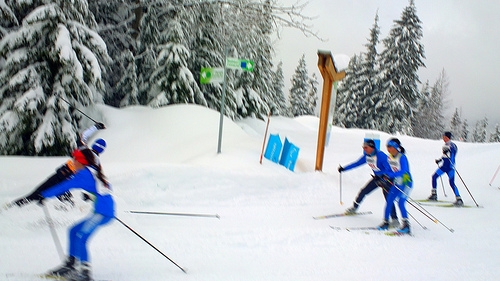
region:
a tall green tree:
[362, 1, 432, 134]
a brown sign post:
[298, 40, 360, 190]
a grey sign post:
[202, 48, 247, 160]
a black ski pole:
[74, 181, 208, 278]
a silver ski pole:
[376, 166, 459, 248]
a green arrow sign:
[191, 58, 228, 88]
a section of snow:
[188, 170, 264, 242]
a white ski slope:
[21, 84, 489, 278]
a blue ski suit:
[371, 141, 426, 238]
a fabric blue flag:
[249, 111, 344, 186]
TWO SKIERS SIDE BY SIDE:
[307, 126, 457, 250]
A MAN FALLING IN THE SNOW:
[1, 85, 121, 212]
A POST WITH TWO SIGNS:
[192, 35, 260, 162]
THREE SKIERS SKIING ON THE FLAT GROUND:
[307, 109, 485, 240]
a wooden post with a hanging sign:
[300, 42, 361, 185]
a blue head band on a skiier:
[383, 135, 404, 152]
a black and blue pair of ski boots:
[374, 213, 419, 240]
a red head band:
[68, 145, 96, 170]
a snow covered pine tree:
[351, 0, 435, 135]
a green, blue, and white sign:
[220, 55, 263, 77]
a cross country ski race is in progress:
[9, 127, 496, 274]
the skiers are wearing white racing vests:
[73, 143, 474, 204]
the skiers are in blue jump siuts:
[32, 134, 462, 254]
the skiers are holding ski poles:
[61, 139, 498, 264]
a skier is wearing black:
[4, 97, 114, 204]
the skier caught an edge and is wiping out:
[11, 101, 114, 201]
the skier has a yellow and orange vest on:
[65, 140, 91, 179]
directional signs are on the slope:
[198, 49, 258, 169]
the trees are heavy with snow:
[6, 2, 499, 237]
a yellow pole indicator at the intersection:
[283, 45, 353, 177]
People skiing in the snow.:
[10, 76, 493, 276]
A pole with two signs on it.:
[180, 17, 250, 157]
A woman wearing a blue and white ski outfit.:
[32, 140, 137, 275]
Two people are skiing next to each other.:
[325, 125, 435, 242]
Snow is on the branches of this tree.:
[5, 1, 100, 138]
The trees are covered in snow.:
[10, 6, 485, 136]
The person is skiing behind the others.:
[421, 121, 476, 206]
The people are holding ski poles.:
[321, 115, 461, 252]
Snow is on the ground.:
[234, 222, 321, 279]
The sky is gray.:
[447, 7, 496, 58]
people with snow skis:
[328, 124, 492, 246]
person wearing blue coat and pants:
[382, 132, 432, 242]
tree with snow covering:
[381, 5, 436, 148]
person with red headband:
[56, 136, 124, 196]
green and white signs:
[191, 41, 258, 149]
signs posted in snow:
[182, 44, 262, 181]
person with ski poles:
[372, 123, 476, 253]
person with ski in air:
[21, 79, 118, 206]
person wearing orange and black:
[51, 101, 110, 197]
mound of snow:
[126, 100, 256, 181]